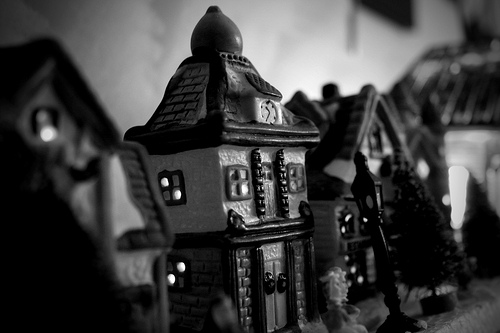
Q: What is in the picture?
A: Buildings.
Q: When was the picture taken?
A: Over winter.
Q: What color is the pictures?
A: Black and white.